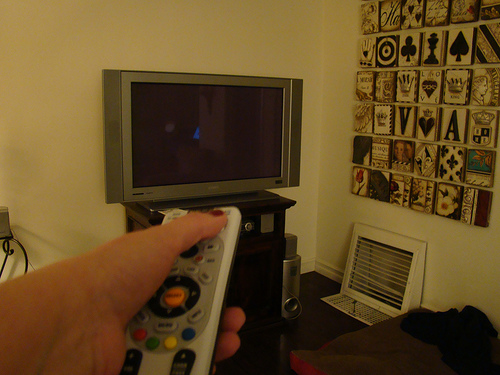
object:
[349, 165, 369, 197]
art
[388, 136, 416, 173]
art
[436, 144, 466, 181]
art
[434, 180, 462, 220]
art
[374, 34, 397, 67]
art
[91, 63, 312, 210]
television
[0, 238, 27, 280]
scroll work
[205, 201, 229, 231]
nail polish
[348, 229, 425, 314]
ventilation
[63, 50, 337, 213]
television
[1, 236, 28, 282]
wires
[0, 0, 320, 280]
wall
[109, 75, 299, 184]
tv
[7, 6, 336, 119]
wall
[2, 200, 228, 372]
hand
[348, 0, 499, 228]
artwork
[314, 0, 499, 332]
wall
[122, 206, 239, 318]
remote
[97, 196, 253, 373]
controller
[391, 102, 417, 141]
tile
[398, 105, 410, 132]
v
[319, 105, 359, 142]
ground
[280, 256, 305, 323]
speaker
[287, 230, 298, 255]
speaker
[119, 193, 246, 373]
remote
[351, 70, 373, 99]
tiles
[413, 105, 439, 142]
tiles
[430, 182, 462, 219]
tiles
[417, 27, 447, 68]
tiles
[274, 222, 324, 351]
console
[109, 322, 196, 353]
buttons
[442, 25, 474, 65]
tile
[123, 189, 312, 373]
stand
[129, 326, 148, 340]
red button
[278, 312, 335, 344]
floor